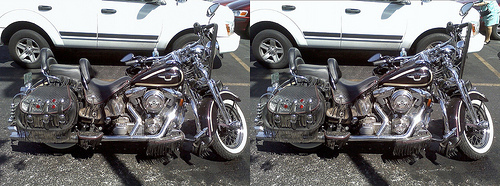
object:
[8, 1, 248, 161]
bike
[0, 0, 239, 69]
car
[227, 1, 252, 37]
car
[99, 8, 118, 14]
door handles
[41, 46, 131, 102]
seat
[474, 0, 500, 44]
woman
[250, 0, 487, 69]
car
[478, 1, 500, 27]
dress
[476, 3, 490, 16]
handbag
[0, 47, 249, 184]
pavement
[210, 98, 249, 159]
wheel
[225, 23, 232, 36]
orange light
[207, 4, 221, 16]
mirror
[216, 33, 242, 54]
bumper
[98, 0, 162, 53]
door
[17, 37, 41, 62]
rim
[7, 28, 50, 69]
wheel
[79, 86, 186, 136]
engine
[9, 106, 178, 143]
exhaust pipe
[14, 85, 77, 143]
saddlebag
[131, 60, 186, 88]
gas tank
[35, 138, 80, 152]
rear wheel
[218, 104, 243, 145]
spokes